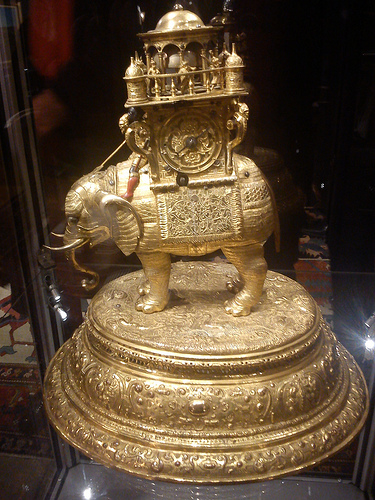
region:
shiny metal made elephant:
[67, 190, 253, 238]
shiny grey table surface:
[32, 477, 125, 494]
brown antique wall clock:
[159, 117, 236, 170]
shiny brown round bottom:
[67, 378, 369, 467]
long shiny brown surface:
[29, 266, 74, 342]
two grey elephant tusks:
[45, 231, 70, 249]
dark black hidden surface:
[280, 19, 371, 132]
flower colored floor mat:
[5, 370, 41, 440]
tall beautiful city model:
[118, 0, 262, 156]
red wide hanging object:
[29, 0, 74, 76]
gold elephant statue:
[43, 2, 369, 487]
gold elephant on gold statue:
[41, 145, 284, 320]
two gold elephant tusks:
[36, 216, 99, 255]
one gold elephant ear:
[90, 189, 140, 254]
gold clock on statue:
[130, 107, 245, 176]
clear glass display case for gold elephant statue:
[0, 0, 370, 496]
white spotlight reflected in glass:
[352, 325, 370, 356]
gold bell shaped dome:
[122, 1, 231, 37]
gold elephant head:
[38, 165, 138, 293]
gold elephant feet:
[129, 270, 265, 315]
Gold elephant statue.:
[74, 135, 301, 293]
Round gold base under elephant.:
[79, 287, 297, 494]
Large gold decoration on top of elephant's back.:
[124, 38, 244, 201]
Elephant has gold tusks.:
[40, 212, 105, 295]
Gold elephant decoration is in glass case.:
[80, 107, 352, 397]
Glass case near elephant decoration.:
[25, 433, 106, 498]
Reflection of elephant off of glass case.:
[252, 120, 312, 238]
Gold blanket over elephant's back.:
[163, 185, 322, 282]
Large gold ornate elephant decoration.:
[45, 346, 364, 468]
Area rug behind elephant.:
[6, 282, 22, 377]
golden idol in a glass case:
[5, 2, 369, 499]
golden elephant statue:
[52, 3, 350, 471]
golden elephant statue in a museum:
[3, 1, 367, 496]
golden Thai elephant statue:
[8, 0, 370, 493]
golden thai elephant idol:
[30, 6, 358, 484]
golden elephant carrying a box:
[43, 3, 306, 330]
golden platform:
[28, 259, 373, 481]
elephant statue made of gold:
[49, 148, 294, 318]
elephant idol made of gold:
[2, 0, 353, 475]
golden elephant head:
[53, 163, 136, 314]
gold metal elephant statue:
[33, 131, 319, 346]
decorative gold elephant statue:
[34, 6, 306, 346]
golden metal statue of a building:
[114, 1, 261, 215]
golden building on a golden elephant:
[48, 0, 268, 322]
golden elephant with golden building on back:
[46, 0, 281, 353]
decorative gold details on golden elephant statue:
[41, 130, 280, 322]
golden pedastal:
[24, 273, 358, 466]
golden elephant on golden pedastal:
[98, 135, 335, 497]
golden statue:
[27, 9, 339, 457]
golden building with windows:
[85, 9, 259, 142]